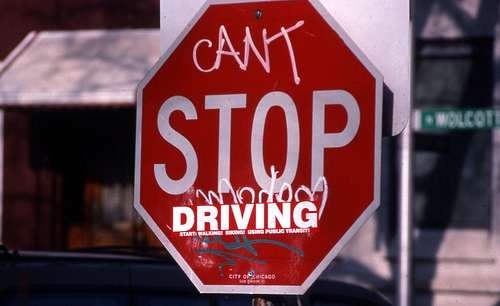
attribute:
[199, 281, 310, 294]
border — white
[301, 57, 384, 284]
border — white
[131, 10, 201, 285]
border — white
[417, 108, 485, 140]
street sign — white, green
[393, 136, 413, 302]
pole — metal, street sign, support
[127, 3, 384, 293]
stop sign — vandalized, red, octagon shaped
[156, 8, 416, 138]
sign — white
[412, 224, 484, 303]
structure — concrete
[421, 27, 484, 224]
shadow — of tree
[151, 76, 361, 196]
written — bold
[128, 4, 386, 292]
shape — hexagonal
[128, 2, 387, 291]
poster — bright, red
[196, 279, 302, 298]
border — white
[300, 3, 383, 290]
border — white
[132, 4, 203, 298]
border — white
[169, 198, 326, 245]
bumper sticker — white, red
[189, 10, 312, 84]
graffiti — white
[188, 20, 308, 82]
contraction — common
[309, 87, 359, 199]
p — capital, large, white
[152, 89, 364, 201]
font — sans-serif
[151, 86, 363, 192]
font — sans-serif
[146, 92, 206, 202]
s — large, white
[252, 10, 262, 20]
bolt — grey, metal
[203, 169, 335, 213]
graffiti — older, irrelevant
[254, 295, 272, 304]
pole — metal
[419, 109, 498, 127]
background — green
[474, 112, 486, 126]
letter — white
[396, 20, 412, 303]
pole — white, metal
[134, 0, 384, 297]
border — white, octagonal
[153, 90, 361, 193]
"stop" — big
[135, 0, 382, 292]
street sign — red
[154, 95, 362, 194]
letters — large, white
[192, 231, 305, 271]
graffiti — gray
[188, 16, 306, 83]
graffiti — white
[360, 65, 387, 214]
edging — white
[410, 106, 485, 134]
street sign — green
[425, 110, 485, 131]
lettering — white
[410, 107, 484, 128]
sign — green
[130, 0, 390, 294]
sign — red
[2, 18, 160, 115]
roof — short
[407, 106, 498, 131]
sign — blurry, green